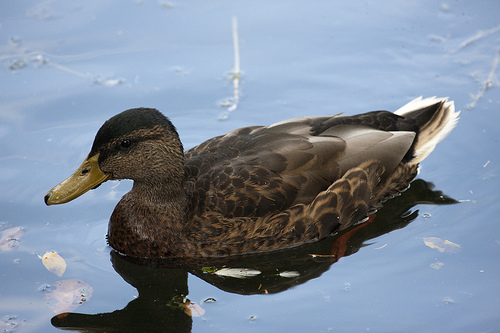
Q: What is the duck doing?
A: Floating on the water.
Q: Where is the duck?
A: On the water.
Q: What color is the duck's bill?
A: Yellow.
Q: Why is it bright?
A: It's daytime.